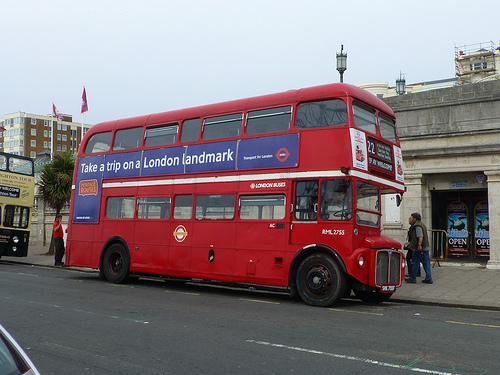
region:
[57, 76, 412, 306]
a red double-decker bus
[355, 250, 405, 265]
headlights of double-decker bus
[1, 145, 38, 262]
a yellow double-decker bus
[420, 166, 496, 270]
a door is open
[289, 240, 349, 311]
front tires of double-decker bus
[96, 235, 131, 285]
back tires of double-decker bus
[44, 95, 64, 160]
a flag hangs on white pole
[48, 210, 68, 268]
man wears a red shirt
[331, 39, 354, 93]
a light behind a bus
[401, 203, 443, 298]
people walking on sidewalk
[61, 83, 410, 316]
the bus is big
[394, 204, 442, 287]
people standing on the sidewalk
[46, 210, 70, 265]
the person is wearing a white shirt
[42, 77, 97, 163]
flags on flag poles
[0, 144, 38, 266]
the bus is black and yellow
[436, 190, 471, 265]
the door says open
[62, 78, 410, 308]
the bus is red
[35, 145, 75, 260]
a tree behind the bus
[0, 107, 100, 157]
the building is brown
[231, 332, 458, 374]
the road has a white line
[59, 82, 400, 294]
A parked double decker bus.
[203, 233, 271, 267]
The bus is red.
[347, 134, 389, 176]
22 on the bus.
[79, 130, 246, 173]
Sign on the side of the bus.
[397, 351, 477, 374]
Green on the road.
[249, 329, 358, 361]
White on the road.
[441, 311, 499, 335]
Yellow on the road.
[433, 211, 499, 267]
There are two signs that say open.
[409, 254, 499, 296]
The sidewalk is brick.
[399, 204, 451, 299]
Two people walking on the sidewalk.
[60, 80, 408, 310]
A bus is parked on a street.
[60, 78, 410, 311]
A bus is parked on a road.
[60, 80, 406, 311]
The colors of a bus are red, black, blue, white, and yellow.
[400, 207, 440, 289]
Two men are near a bus.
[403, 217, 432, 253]
A man is wearing a tan jacket.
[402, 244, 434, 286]
A man is wearing blue pants.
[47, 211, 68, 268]
A man is behind a bus.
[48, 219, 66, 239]
A man is wearing a red shirt.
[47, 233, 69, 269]
A man is wearing dark pants.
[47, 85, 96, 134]
Flags are in the background.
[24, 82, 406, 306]
double deck red bus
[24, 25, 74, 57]
white clouds in blue sky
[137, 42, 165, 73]
white clouds in blue sky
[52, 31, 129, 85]
white clouds in blue sky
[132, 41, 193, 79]
white clouds in blue sky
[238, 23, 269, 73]
white clouds in blue sky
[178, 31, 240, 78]
white clouds in blue sky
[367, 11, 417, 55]
white clouds in blue sky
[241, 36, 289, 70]
white clouds in blue sky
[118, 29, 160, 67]
white clouds in blue sky